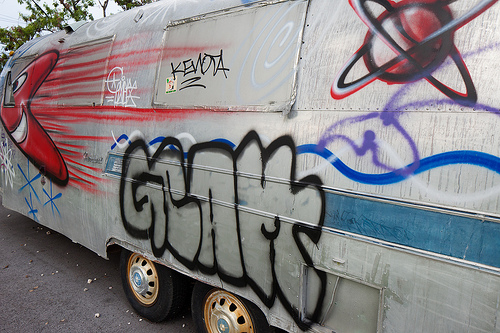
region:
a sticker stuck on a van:
[149, 58, 206, 123]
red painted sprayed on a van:
[43, 47, 106, 150]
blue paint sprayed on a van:
[418, 147, 456, 187]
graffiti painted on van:
[152, 40, 348, 285]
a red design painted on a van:
[10, 59, 74, 191]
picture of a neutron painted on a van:
[354, 34, 489, 96]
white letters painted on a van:
[103, 64, 148, 127]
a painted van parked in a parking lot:
[16, 35, 313, 332]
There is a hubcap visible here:
[216, 298, 231, 330]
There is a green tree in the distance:
[18, 10, 35, 48]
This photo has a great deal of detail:
[111, 36, 223, 309]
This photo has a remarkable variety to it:
[125, 61, 210, 315]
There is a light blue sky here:
[8, 4, 13, 16]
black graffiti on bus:
[115, 146, 344, 291]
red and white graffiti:
[0, 61, 82, 185]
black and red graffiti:
[283, 2, 483, 96]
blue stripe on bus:
[315, 174, 499, 260]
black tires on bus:
[120, 244, 275, 329]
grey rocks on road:
[46, 254, 178, 330]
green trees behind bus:
[3, 2, 110, 52]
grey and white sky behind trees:
[7, 7, 41, 39]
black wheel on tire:
[117, 247, 185, 322]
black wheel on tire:
[190, 282, 270, 331]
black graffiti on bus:
[120, 140, 322, 327]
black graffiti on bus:
[171, 50, 228, 88]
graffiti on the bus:
[325, 1, 497, 101]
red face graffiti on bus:
[0, 47, 67, 184]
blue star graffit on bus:
[15, 165, 60, 225]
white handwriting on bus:
[102, 67, 137, 107]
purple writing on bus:
[318, 52, 498, 169]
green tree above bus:
[0, 0, 112, 55]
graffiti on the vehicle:
[1, 60, 111, 167]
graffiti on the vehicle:
[16, 168, 91, 237]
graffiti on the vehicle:
[95, 129, 189, 259]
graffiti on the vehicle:
[281, 231, 366, 329]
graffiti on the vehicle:
[238, 129, 323, 188]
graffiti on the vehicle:
[345, 0, 497, 100]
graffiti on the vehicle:
[398, 63, 494, 126]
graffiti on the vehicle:
[317, 103, 424, 184]